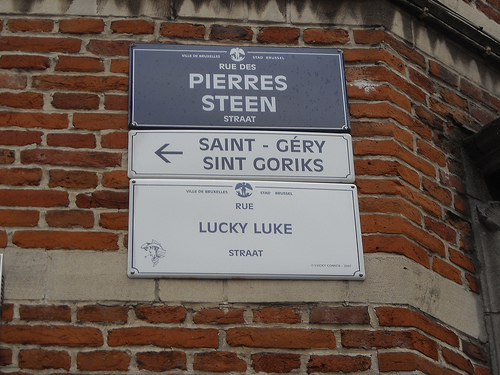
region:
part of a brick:
[284, 326, 304, 348]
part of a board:
[314, 255, 316, 262]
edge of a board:
[167, 253, 178, 268]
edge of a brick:
[193, 307, 210, 339]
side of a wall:
[421, 220, 431, 248]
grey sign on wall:
[128, 44, 350, 130]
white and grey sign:
[127, 129, 354, 180]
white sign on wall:
[128, 179, 367, 278]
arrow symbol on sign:
[156, 144, 183, 163]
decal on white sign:
[142, 239, 167, 267]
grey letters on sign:
[198, 219, 292, 235]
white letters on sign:
[188, 72, 287, 114]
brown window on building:
[456, 141, 499, 373]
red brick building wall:
[1, 12, 498, 374]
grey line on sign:
[263, 143, 269, 149]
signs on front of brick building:
[107, 30, 379, 297]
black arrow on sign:
[142, 137, 189, 167]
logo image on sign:
[230, 180, 255, 200]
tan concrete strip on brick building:
[3, 236, 488, 348]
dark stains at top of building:
[260, 0, 405, 40]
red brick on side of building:
[15, 98, 99, 234]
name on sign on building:
[186, 215, 318, 250]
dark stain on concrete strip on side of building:
[403, 268, 458, 316]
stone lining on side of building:
[451, 147, 497, 374]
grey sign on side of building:
[122, 38, 366, 135]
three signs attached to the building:
[123, 34, 363, 274]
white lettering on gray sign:
[173, 48, 302, 134]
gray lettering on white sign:
[150, 131, 347, 273]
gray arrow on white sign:
[152, 142, 181, 167]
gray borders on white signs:
[123, 130, 365, 282]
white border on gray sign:
[128, 47, 350, 135]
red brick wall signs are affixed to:
[5, 13, 480, 373]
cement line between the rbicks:
[2, 238, 491, 335]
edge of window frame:
[453, 113, 499, 359]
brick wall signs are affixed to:
[0, 17, 485, 367]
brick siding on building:
[5, 19, 125, 241]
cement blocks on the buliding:
[7, 248, 146, 304]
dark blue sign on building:
[135, 42, 349, 139]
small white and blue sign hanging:
[135, 130, 354, 183]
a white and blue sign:
[132, 178, 369, 277]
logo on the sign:
[131, 234, 174, 271]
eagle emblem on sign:
[234, 180, 255, 199]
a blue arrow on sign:
[152, 133, 192, 174]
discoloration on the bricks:
[342, 78, 386, 94]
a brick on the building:
[418, 175, 458, 203]